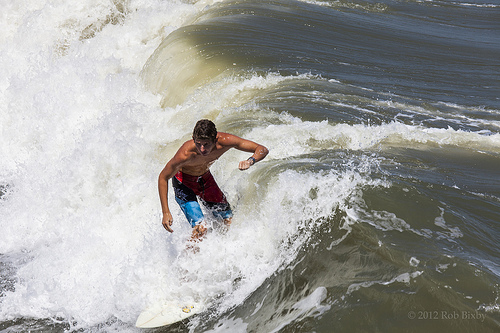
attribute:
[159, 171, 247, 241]
shorts — Dark black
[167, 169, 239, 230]
shorts — Red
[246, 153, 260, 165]
wrist — person's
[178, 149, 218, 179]
chested —  bare 